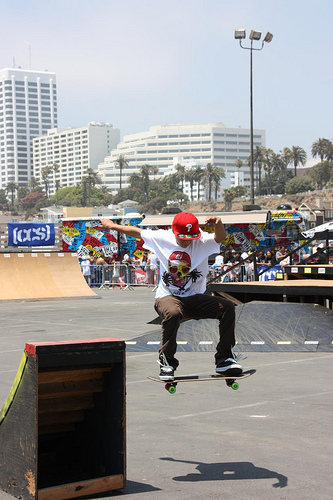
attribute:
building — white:
[30, 119, 120, 199]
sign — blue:
[6, 219, 56, 248]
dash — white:
[198, 340, 212, 344]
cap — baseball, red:
[170, 208, 201, 242]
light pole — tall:
[225, 17, 293, 223]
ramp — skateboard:
[9, 316, 137, 393]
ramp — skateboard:
[0, 337, 127, 497]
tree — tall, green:
[282, 141, 309, 178]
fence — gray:
[79, 265, 155, 284]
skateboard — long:
[155, 356, 251, 398]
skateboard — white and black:
[146, 367, 255, 391]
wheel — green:
[163, 379, 185, 407]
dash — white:
[249, 322, 302, 388]